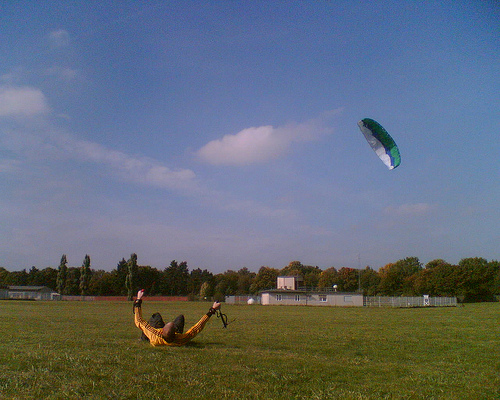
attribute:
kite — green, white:
[354, 113, 409, 175]